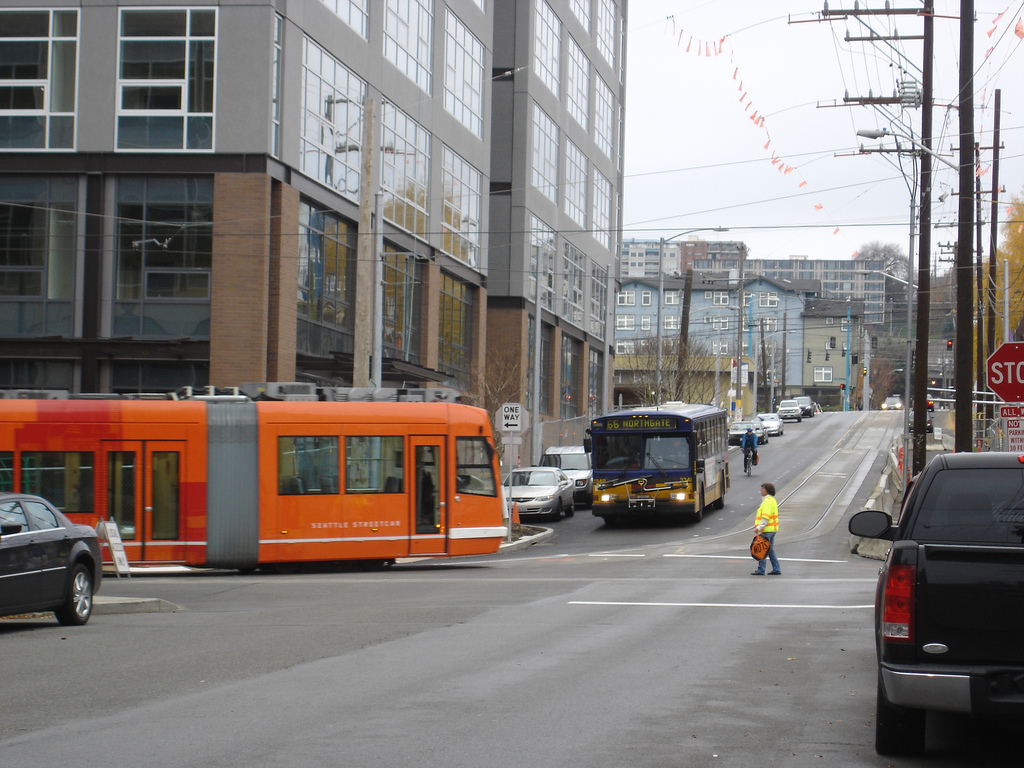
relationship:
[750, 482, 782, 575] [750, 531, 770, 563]
crossing guard holding sign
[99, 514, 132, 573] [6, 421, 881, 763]
sign sitting in street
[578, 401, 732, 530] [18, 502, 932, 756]
bus in street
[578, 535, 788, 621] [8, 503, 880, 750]
crosswalk on road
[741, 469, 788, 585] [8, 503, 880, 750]
guard on road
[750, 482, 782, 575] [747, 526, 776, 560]
crossing guard has sign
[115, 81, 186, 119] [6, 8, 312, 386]
window on building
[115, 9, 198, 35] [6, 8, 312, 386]
window on building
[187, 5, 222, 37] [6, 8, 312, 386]
window on building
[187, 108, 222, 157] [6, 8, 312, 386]
window on building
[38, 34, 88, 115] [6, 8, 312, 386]
window on building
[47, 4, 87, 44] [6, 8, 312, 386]
window on building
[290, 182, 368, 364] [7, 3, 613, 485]
window on building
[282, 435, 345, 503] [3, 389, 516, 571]
window on bus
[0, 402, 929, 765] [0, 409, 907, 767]
truck parked on side of road